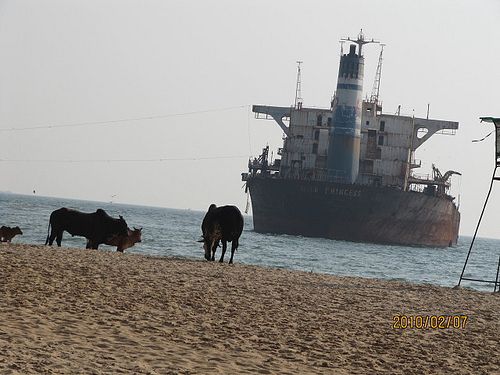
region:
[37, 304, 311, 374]
Beige sand on a beach.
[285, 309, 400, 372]
Animal tracks on a beach.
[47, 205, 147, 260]
Oxen eating from the ground.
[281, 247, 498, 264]
Blue colored ocean water.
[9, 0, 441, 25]
A gray colored cloudy sky.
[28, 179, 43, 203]
A lighthouse in the background.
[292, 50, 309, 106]
A communication tower on a oil rig.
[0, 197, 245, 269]
Three oxen grazing on the beach.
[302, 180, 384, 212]
White letters on an oil rig.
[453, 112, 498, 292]
Photography equiptment on a beach.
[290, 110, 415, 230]
A cargo ship in the water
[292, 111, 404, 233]
Ship near the shore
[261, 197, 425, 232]
Ship floating in the water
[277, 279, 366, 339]
A sandy beach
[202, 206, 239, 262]
A cow on a sandy beach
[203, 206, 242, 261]
A cow near the water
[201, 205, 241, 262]
A cow near a ship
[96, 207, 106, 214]
The hump of a bull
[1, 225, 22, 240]
A small cow on the beach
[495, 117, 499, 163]
A raised look out platform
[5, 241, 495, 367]
tan sand filled with footprints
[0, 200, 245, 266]
dark cows standing on sand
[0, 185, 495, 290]
rippled blue-gray water of ocean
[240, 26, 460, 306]
large ship close to beach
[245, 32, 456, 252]
tower in center of boat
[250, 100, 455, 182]
extended platform over floors of structure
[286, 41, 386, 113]
metal towers on boat platform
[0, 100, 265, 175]
horizontal wires attached to ship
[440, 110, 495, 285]
thin legs of elevated structure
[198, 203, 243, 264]
animal smelling the ground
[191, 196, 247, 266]
a black cow on the beach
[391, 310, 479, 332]
a date stamp for 2010/02/07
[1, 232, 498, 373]
a sandy beach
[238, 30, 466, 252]
a large ship named princess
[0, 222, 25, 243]
a black cow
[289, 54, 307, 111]
a communication tower on the ship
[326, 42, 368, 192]
a smoke stack on the ship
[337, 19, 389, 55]
a radar on the ship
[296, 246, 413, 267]
Waves on an ocean.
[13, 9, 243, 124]
A gray cloudless sky.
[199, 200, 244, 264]
An oxen with its head down.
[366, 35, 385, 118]
Communication tower on an oil rig.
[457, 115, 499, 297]
Camera equiptment on dry land.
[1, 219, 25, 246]
A baby oxen running on the beach.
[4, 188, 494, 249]
Horizon where the sky meets dry land.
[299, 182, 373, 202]
Barely visible markings on the side of an oil rig.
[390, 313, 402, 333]
yellow print style number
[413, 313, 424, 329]
yellow print style number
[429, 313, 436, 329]
yellow print style number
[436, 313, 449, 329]
yellow print style number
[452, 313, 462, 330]
yellow print style number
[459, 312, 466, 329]
yellow print style number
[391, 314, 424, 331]
yellow print style number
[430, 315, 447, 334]
yellow print style number